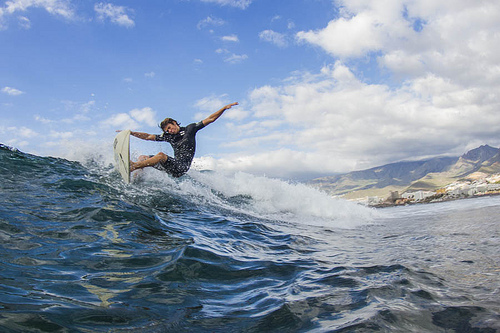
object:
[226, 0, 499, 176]
clouds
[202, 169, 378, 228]
foam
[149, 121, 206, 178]
wet suit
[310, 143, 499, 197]
mountain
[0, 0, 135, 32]
clouds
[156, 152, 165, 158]
knee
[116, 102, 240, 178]
man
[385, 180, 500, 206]
buildings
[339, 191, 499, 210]
coast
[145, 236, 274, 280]
waves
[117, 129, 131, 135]
tip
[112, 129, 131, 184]
surfboard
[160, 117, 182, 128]
hair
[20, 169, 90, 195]
wave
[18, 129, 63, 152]
clouds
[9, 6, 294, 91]
sky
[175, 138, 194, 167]
navy blue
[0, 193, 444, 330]
water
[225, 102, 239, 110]
hand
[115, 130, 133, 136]
hand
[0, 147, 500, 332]
ocean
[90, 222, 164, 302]
reflection